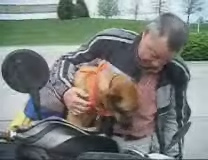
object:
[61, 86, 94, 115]
hand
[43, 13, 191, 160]
man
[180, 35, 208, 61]
bush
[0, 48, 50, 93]
mirror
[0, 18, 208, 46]
lawn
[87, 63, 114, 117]
bandanna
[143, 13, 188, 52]
hair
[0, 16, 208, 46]
grass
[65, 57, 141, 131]
brown dog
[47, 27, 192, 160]
coat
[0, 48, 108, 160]
bike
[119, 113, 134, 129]
nose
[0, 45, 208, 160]
street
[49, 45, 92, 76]
elbow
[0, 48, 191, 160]
motorcycle